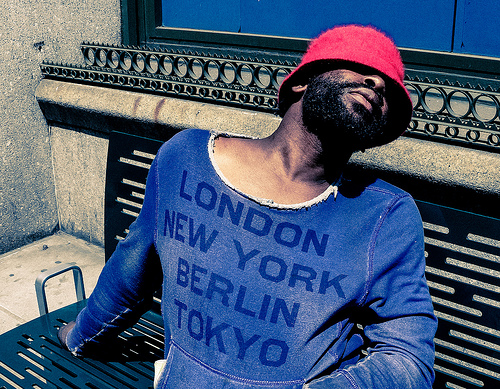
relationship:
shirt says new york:
[63, 124, 437, 388] [149, 206, 358, 306]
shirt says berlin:
[63, 124, 437, 388] [161, 257, 307, 331]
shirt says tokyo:
[62, 124, 441, 386] [172, 298, 288, 368]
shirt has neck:
[63, 124, 437, 388] [197, 115, 365, 235]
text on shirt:
[157, 167, 351, 374] [62, 124, 441, 386]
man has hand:
[55, 22, 438, 387] [58, 321, 75, 346]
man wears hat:
[55, 22, 438, 387] [275, 24, 412, 146]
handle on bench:
[35, 272, 73, 305] [0, 128, 497, 385]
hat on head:
[275, 24, 412, 146] [289, 67, 391, 156]